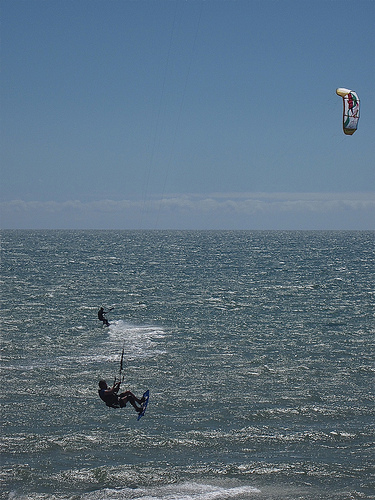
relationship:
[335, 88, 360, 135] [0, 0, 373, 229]
kite in sky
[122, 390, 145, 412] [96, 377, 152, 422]
legs of man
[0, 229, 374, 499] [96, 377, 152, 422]
water under man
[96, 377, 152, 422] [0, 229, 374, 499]
man above water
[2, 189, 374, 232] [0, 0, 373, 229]
clouds in sky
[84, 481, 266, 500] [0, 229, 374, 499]
wave in water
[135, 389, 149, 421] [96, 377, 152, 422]
board on man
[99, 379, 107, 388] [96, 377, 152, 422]
head of man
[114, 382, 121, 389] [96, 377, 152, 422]
hands of man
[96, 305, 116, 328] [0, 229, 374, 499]
man in water